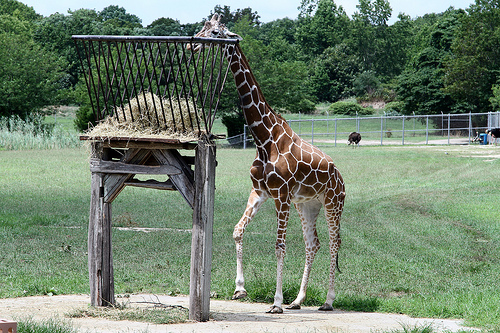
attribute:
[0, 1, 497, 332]
photo — taken outside, daytime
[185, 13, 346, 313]
giraffe — eating, tall, brown, standing, white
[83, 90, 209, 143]
hay — food, brown, yellow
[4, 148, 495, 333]
grass — mowed, green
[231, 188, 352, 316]
legs — long, white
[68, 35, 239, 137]
container — black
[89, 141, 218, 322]
legs — wood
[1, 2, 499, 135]
trees — green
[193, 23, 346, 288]
spots — brown, white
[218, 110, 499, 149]
fence — chain link, gray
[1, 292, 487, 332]
dirt — tan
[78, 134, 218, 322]
support — wood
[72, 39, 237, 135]
bars — black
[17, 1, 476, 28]
sky — blue